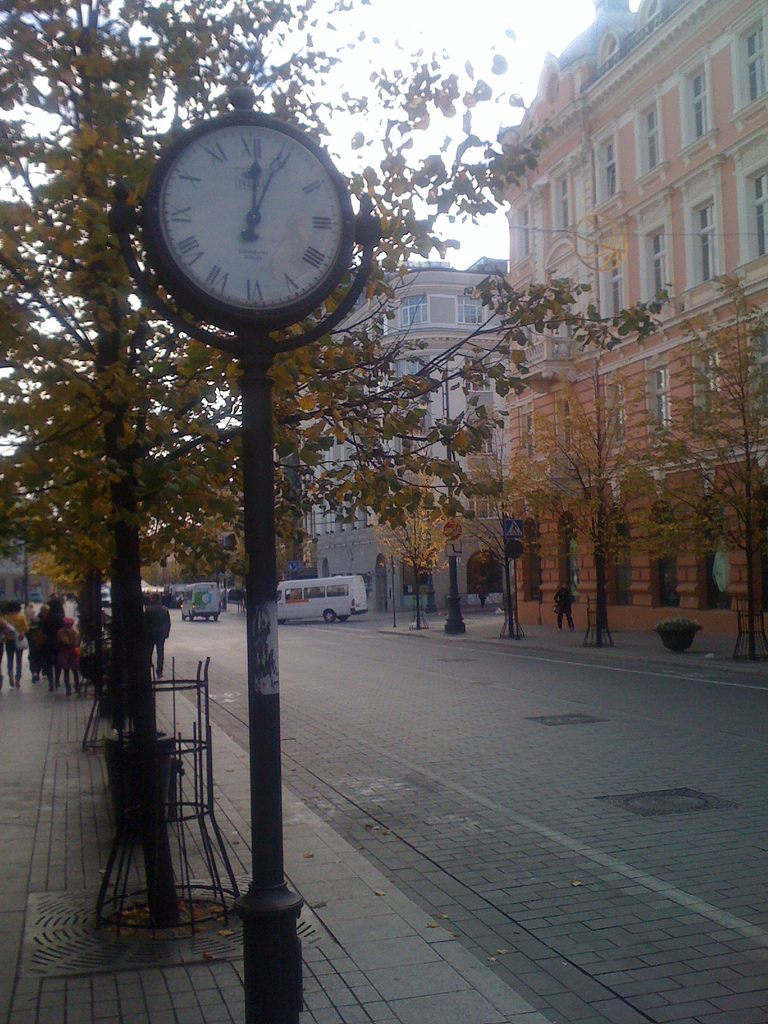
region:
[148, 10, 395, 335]
the clock has a white face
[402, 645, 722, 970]
the street is made of brick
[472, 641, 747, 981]
the bricks are grey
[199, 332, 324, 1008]
the pole is made of metal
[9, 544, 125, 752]
people are walking on the sidewalk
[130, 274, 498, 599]
the leaves are changing color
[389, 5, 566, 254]
the sky is white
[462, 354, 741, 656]
the building is a rusty orange color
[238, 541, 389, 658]
a car is driving on the street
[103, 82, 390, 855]
white clock on black pole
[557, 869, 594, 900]
brown leaf on grey brick street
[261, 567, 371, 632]
white van making right turn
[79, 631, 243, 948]
black iorn railing around tree trunk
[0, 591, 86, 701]
group of people walking north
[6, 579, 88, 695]
group of people walking on sidewalk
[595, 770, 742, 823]
metal manhole cove on street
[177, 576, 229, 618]
white van with left turn signal on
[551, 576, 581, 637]
woman in black carrying brown purse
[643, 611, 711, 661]
large black flower pot on sidewalk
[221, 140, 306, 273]
Hands on the clock are black.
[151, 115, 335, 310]
Numbers on clock are black.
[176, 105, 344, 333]
Face of clock is white in color.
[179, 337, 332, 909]
Clock is attached to tall black pole.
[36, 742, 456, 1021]
Sidewalk is made of bricks.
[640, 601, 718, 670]
Large black pot full of flowers on sidewalk.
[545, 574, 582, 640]
Person wearing all black standing on sidewalk.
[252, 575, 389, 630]
White van driving on road.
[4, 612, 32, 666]
White cross body bag around person's shoulder.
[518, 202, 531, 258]
window in front of building facing street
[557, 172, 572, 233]
window in front of building facing street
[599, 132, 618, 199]
window in front of building facing street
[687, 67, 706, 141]
window in front of building facing street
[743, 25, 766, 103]
window in front of building facing street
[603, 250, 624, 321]
window in front of building facing street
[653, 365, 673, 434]
window in front of building facing street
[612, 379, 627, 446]
window in front of building facing street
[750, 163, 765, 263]
window in front of building facing street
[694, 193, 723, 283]
window in front of building facing street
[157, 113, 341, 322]
black and white clock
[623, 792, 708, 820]
sewer lid on street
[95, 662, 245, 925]
the cage is black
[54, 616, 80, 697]
a person is standing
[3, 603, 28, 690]
a person is standing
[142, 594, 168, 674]
a person is standing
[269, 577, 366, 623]
a bus is driving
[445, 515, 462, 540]
red and white sign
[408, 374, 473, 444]
green leaves on the tree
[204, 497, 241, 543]
green leaves on the tree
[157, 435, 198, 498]
green leaves on the tree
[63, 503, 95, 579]
green leaves on the tree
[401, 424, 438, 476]
green leaves on the tree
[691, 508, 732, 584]
green leaves on the tree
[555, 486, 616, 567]
green leaves on the tree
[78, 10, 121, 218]
green leaves on the tree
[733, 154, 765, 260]
glass window on building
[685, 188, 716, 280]
glass window on building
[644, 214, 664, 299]
glass window on building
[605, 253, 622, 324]
glass window on building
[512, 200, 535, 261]
glass window on building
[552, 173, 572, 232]
glass window on building